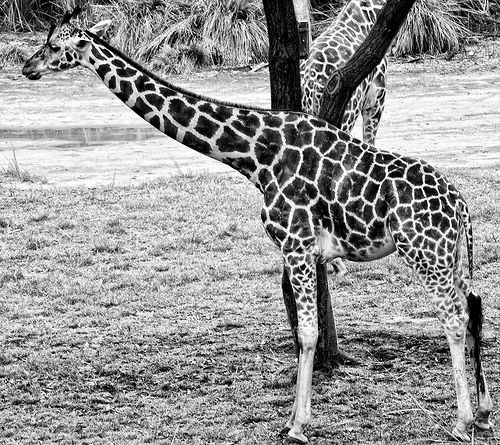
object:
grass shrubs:
[0, 0, 499, 78]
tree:
[262, 0, 413, 369]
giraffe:
[22, 4, 495, 445]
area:
[0, 125, 499, 443]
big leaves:
[110, 0, 269, 74]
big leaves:
[390, 0, 500, 56]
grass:
[0, 140, 499, 444]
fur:
[89, 38, 493, 430]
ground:
[0, 0, 500, 444]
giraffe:
[299, 0, 388, 278]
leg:
[361, 67, 386, 146]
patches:
[431, 212, 450, 234]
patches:
[300, 264, 307, 271]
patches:
[371, 107, 377, 116]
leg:
[453, 229, 494, 412]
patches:
[459, 280, 464, 289]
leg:
[393, 238, 474, 424]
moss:
[2, 80, 271, 184]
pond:
[0, 96, 500, 177]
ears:
[88, 19, 112, 37]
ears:
[74, 39, 92, 52]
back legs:
[388, 223, 493, 422]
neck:
[92, 35, 263, 194]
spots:
[317, 158, 344, 200]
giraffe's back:
[305, 114, 455, 191]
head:
[22, 10, 94, 80]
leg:
[284, 256, 318, 407]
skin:
[278, 138, 463, 267]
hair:
[466, 291, 490, 360]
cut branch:
[326, 72, 341, 95]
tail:
[448, 185, 484, 409]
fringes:
[427, 269, 450, 316]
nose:
[24, 60, 33, 68]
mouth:
[23, 71, 36, 79]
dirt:
[176, 64, 268, 90]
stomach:
[312, 203, 396, 263]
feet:
[278, 426, 311, 445]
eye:
[48, 43, 61, 53]